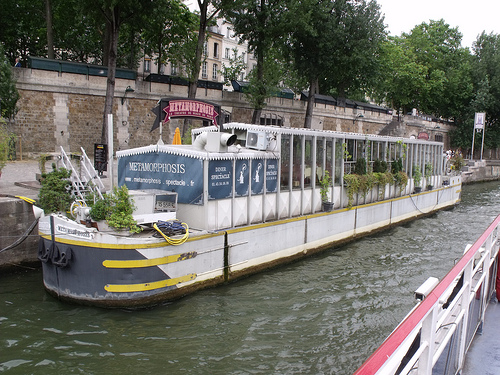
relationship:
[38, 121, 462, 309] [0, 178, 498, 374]
structure next to water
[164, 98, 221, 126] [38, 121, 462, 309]
sign next to structure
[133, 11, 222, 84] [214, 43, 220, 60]
building has window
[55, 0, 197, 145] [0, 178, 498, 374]
tree above water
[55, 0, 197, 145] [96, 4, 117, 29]
tree has branch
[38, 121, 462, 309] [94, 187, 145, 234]
structure has vegetation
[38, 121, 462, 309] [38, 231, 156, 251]
structure has strip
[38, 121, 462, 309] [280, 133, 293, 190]
structure has window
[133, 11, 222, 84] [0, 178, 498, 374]
building by water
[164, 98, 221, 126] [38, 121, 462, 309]
sign for structure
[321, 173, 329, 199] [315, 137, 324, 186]
vegetation on window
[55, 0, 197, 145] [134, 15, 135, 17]
tree has leaf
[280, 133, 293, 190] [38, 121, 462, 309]
window on side of structure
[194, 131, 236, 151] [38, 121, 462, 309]
tube on top of structure